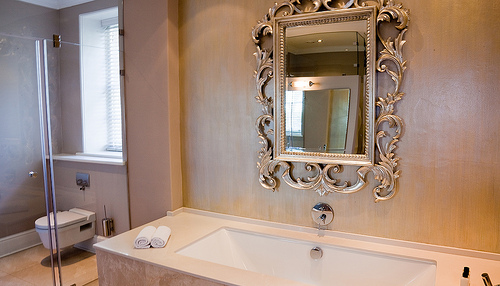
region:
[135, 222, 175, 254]
Towels in the photo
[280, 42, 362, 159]
Mirror in the photo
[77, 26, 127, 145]
Window in the photo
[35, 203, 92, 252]
Toilet seat in the photo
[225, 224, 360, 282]
A bathtub in the photo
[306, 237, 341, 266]
Tap on the bathtub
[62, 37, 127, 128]
Light on the window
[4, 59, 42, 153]
A wall in the bathroom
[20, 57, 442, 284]
A bathroom in the photo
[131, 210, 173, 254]
Two towels on the bathtub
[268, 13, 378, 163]
The mirror is rectangular.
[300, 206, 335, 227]
The faucet is silver.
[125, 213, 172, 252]
The towels are white.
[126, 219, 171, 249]
The towels are on the tub.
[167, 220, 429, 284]
The tub is white.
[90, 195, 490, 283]
The tub shelf is tan.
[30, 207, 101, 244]
The toilet is white.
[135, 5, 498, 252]
The wall is tan.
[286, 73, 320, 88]
The light is on.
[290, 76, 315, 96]
The lights is yellow.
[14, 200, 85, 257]
Toilet is white color.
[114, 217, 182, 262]
Towel is in the tub slab.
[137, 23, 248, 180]
Wall is brown color.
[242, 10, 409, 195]
Mirror is attached to the wall.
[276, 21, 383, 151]
Reflection is seen in mirror.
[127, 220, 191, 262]
Towel is white color.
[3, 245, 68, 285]
Floor is brown color.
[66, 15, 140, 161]
Window shutter is white color.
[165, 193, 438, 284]
Tub is white color.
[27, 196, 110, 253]
Toilet is attached to the wall.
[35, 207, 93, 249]
The toilet is white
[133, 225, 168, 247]
Wash cloths on the sink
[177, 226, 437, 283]
The sink is white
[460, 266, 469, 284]
A bottle of something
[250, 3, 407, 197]
A fancy looking mirror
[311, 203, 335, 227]
The faucet is silver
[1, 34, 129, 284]
The door is clear glass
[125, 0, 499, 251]
The wall is brown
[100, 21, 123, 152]
The blinds are white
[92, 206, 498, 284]
The counter is light colored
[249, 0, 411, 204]
A bathroom wall mirror with an ivy designed frame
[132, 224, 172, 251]
A couple of face towels rolled up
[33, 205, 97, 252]
A white porcelain toilet with the lid down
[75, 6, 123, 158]
A white framed window with horizontal blinds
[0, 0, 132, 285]
A glass room divider with metal brackets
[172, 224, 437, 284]
A large rectangular white bathroom sink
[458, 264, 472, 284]
A couple of small bottles with black lids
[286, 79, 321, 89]
A horizontal light feature attached to the wall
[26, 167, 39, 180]
A silver metal door knob on a glass door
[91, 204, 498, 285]
A long cream colored bathroom vanity